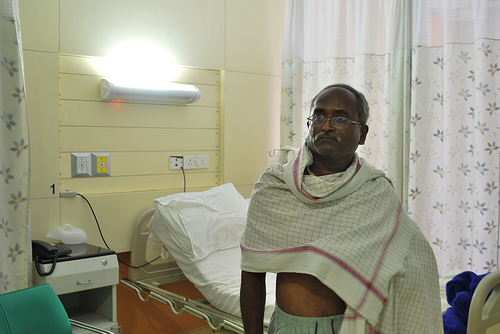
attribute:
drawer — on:
[44, 253, 126, 300]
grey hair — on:
[309, 81, 371, 115]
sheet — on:
[246, 150, 442, 332]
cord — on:
[52, 193, 159, 247]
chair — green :
[0, 282, 72, 332]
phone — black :
[24, 230, 71, 277]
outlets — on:
[165, 148, 214, 178]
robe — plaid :
[237, 151, 441, 333]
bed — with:
[134, 177, 251, 294]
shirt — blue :
[431, 259, 496, 329]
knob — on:
[71, 275, 108, 289]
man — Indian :
[230, 81, 402, 286]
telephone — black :
[28, 237, 73, 276]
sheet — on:
[336, 221, 387, 259]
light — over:
[98, 80, 208, 110]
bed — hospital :
[151, 186, 248, 306]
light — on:
[86, 68, 206, 105]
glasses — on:
[303, 109, 375, 142]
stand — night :
[33, 258, 135, 331]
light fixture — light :
[100, 75, 204, 103]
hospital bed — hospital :
[120, 184, 483, 332]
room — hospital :
[0, 0, 480, 331]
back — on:
[10, 280, 63, 330]